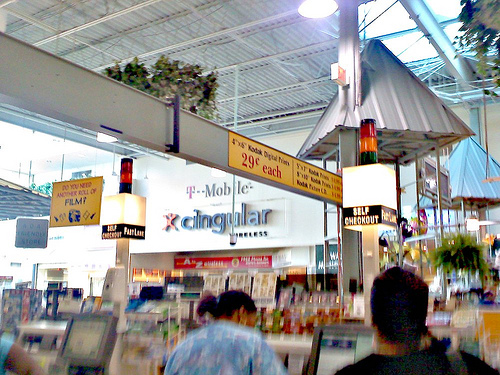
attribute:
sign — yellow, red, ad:
[221, 122, 347, 202]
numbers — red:
[239, 153, 287, 185]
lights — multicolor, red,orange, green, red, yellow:
[358, 117, 380, 160]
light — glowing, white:
[99, 128, 119, 150]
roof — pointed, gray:
[297, 40, 475, 158]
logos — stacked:
[169, 180, 275, 243]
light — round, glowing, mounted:
[294, 0, 339, 29]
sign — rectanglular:
[175, 255, 279, 272]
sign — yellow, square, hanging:
[47, 175, 111, 227]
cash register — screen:
[59, 306, 115, 356]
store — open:
[375, 130, 496, 374]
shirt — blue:
[165, 326, 291, 372]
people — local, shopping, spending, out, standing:
[158, 263, 496, 365]